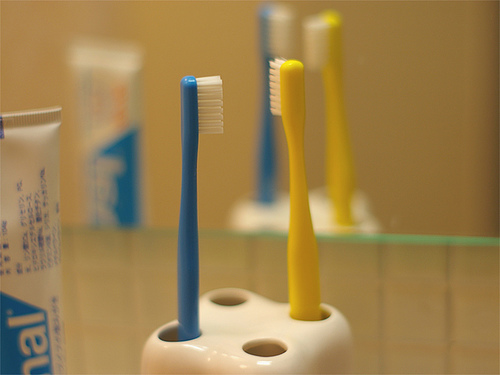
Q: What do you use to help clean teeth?
A: A toothbrush.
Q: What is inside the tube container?
A: Toothpaste.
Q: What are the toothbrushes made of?
A: Plastic,.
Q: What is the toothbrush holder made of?
A: Plastic.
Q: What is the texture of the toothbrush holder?
A: Shiny.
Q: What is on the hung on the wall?
A: A mirror.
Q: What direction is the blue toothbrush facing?
A: The right.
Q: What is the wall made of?
A: Tiles.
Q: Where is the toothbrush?
A: In the holder.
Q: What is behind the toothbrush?
A: The mirror.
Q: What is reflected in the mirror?
A: The toothbrush.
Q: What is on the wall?
A: Mirror.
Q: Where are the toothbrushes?
A: In the holder.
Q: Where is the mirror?
A: On the wall.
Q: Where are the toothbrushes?
A: In the holder.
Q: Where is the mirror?
A: On the wall.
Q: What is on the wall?
A: Tiles.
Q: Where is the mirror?
A: On the wall.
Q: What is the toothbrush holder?
A: Ceramic.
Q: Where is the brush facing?
A: The mirroe.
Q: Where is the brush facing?
A: The right.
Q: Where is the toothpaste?
A: Beside the brushes.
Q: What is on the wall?
A: Mirror.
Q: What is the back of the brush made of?
A: Plastic.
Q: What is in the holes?
A: Toothbrushes.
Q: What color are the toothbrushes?
A: Blue and yellow.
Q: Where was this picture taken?
A: The bathroom.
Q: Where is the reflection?
A: The mirror.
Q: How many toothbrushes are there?
A: Two.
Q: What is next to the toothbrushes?
A: Toothpaste.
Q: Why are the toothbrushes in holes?
A: The holes are a toothbrush holder.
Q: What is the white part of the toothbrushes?
A: Bristles.